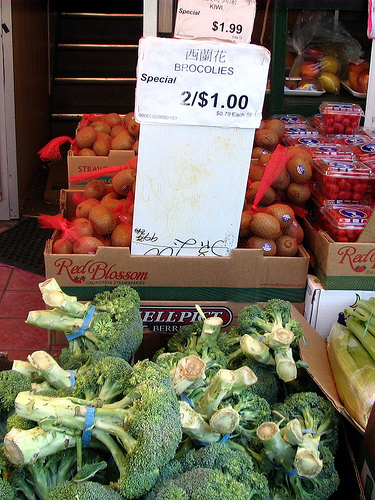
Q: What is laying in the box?
A: Broccoli.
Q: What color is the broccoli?
A: Green.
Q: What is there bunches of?
A: Broccoli stalks.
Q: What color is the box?
A: Brown.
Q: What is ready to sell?
A: Heads of broccoli.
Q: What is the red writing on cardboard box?
A: Red Blossom.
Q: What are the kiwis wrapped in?
A: Mesh bag.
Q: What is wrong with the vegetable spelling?
A: Missing a c.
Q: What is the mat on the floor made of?
A: Rubber.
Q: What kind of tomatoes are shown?
A: Cherry.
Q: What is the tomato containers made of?
A: Plastic.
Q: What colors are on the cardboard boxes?
A: Red and green.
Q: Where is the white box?
A: On right.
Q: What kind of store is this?
A: Vegetables.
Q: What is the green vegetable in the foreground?
A: Broccoli.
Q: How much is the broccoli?
A: Two for $1.00.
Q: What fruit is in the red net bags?
A: Kiwis.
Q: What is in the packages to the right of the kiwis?
A: Grape tomatoes.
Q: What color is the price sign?
A: White.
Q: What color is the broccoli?
A: Green.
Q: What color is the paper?
A: White and pink.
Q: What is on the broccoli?
A: Bands.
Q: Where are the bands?
A: Around the broccoli.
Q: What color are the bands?
A: Blue.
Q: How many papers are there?
A: Three.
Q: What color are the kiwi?
A: Brown.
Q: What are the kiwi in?
A: Nets.